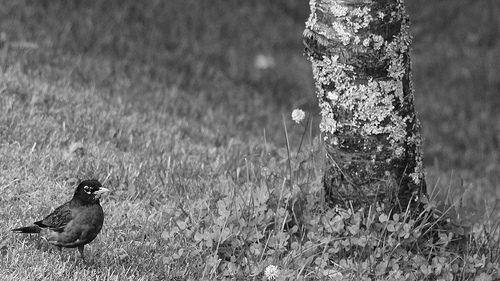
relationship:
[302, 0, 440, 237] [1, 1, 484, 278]
tree stump standing in grass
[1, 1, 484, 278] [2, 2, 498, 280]
grass covering ground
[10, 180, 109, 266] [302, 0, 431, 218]
bird next to tree trunk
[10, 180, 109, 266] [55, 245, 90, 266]
bird has legs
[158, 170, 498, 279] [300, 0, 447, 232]
clovers growing around tree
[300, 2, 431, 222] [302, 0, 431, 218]
bark on tree trunk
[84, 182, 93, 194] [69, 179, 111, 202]
eye on bird's face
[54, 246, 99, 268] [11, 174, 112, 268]
legs on bird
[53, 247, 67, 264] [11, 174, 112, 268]
leg on bird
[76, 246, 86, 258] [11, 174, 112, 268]
legs on bird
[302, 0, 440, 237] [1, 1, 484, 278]
tree stump in grass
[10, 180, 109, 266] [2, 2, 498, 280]
bird on ground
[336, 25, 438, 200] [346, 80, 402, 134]
tree trunk covered in moss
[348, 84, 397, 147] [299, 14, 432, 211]
moss on tree trunk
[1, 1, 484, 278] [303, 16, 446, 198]
grass surrounding tree trunk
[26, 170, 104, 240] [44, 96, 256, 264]
bird in field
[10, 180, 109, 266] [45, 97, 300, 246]
bird on grass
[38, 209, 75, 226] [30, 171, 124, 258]
wing of bird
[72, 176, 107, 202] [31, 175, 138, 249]
head of bird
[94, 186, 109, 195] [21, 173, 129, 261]
beak on bird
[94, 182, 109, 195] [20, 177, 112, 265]
beak on bird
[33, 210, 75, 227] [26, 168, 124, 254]
wing on bird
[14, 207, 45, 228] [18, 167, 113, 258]
feathers on bird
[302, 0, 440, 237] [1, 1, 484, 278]
tree stump in middle of grass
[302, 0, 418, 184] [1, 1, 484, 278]
tree stump in middle of grass